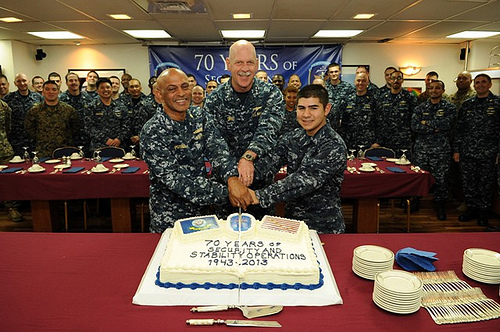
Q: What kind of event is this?
A: Celebration of military service.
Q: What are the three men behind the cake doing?
A: Cutting the cake.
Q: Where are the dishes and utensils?
A: To the right of the cake.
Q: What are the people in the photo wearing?
A: Military uniforms.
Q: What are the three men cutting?
A: Cake.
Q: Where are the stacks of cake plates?
A: On the table.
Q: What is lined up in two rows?
A: Forks.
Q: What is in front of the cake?
A: Knife and spatula.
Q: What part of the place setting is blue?
A: Napkin.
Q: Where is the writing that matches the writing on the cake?
A: On the banner.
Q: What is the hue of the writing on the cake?
A: Blue.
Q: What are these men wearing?
A: Uniforms.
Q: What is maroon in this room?
A: Table cloths.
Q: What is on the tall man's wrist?
A: Watch.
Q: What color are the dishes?
A: White.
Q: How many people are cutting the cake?
A: Three.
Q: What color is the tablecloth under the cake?
A: Red.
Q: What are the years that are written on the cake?
A: 1943-2013.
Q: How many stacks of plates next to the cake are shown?
A: Three.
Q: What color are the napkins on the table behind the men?
A: Blue.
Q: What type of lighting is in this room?
A: Fluorescent.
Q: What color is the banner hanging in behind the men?
A: Blue.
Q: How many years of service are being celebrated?
A: 70.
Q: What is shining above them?
A: Lights on the ceiling.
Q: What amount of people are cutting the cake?
A: Three.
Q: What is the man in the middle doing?
A: Holding the knife.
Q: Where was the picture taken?
A: At the retirement party.